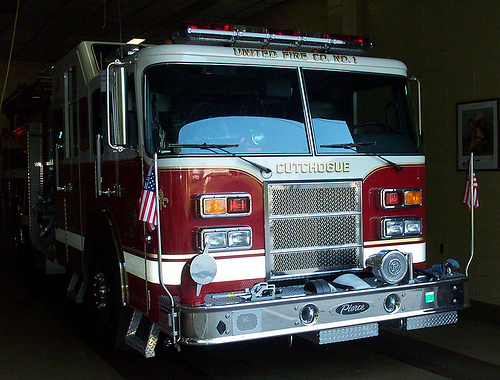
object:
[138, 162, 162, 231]
flag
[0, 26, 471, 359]
truck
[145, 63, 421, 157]
window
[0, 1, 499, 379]
garage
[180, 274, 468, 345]
bumper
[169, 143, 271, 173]
wiper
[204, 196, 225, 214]
signal light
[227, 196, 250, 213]
light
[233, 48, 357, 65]
name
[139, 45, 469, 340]
front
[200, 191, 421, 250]
headlights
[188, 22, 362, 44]
flashing lights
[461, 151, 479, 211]
flag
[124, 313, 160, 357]
step